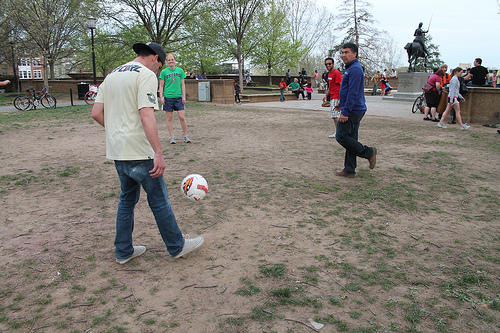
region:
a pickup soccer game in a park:
[11, 8, 411, 314]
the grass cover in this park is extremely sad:
[11, 118, 489, 331]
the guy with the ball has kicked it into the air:
[85, 38, 218, 273]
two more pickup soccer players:
[319, 37, 386, 179]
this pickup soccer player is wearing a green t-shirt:
[156, 48, 199, 148]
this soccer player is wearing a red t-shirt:
[319, 51, 345, 145]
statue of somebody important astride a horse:
[379, 12, 444, 105]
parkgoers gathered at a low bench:
[274, 70, 316, 105]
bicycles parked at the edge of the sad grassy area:
[9, 80, 72, 115]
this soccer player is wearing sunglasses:
[318, 51, 340, 78]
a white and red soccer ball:
[179, 167, 217, 207]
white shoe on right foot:
[153, 231, 218, 268]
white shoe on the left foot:
[112, 237, 151, 273]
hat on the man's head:
[135, 39, 172, 59]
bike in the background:
[7, 81, 63, 115]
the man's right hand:
[144, 147, 168, 179]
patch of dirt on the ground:
[180, 287, 223, 313]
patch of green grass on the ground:
[262, 263, 285, 279]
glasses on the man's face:
[324, 61, 334, 68]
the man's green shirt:
[155, 68, 188, 96]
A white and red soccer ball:
[179, 173, 209, 203]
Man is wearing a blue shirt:
[337, 60, 368, 114]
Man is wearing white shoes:
[175, 235, 206, 257]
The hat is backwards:
[130, 40, 168, 64]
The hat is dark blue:
[131, 38, 166, 63]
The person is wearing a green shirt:
[157, 66, 184, 98]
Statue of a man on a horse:
[404, 20, 431, 75]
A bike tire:
[411, 88, 425, 113]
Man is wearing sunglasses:
[322, 56, 337, 73]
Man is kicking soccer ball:
[89, 40, 210, 266]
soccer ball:
[173, 165, 220, 206]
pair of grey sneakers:
[100, 213, 209, 266]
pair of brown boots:
[331, 143, 379, 179]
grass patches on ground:
[244, 248, 335, 320]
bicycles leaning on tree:
[7, 83, 61, 116]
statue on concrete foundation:
[389, 16, 450, 104]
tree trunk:
[229, 59, 249, 91]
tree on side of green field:
[4, 3, 104, 79]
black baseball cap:
[125, 33, 172, 65]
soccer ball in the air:
[176, 162, 221, 205]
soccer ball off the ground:
[178, 159, 223, 218]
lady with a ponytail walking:
[438, 59, 469, 139]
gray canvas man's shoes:
[106, 227, 211, 274]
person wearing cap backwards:
[116, 24, 168, 78]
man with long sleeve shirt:
[335, 43, 370, 111]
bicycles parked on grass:
[9, 82, 67, 121]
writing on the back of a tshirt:
[78, 32, 166, 87]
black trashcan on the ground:
[73, 65, 95, 109]